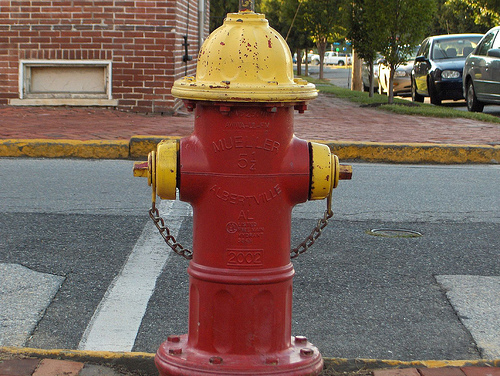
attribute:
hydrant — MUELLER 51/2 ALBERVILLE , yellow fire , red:
[121, 7, 356, 374]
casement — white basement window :
[8, 52, 125, 107]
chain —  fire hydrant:
[140, 196, 338, 270]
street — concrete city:
[384, 167, 447, 281]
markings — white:
[95, 148, 185, 372]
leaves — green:
[375, 9, 383, 16]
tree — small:
[346, 6, 435, 105]